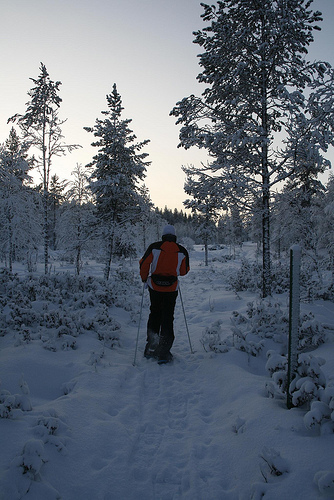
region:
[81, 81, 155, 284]
a snow covered tree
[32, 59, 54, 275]
a snow covered tree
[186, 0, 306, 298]
a snow covered tree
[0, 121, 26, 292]
a snow covered tree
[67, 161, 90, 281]
a snow covered tree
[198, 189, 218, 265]
a snow covered tree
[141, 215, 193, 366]
a long distance skier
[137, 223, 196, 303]
a skier with an orange jacket on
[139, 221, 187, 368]
a skier wearing black pants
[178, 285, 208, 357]
a long black ski pole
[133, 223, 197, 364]
person walking in snow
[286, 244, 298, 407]
post to the right of trail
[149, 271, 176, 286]
person wearing a black fanny pack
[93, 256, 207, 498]
path through the snow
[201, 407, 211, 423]
footprint in the snow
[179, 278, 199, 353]
person holding 2 trekking poles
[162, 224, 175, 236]
white knit hat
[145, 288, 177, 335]
black snow pants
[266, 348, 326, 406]
snow cover shrub next to post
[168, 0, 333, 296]
tall tree to the right of path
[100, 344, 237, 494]
tracks in the snow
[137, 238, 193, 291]
orange, white and black parka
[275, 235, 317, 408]
snow covered pole within brush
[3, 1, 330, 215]
grey sky with early morning light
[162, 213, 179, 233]
white knitted cap with black pom pom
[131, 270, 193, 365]
white snow hiking poles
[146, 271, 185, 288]
black fanny pack around hiker's waist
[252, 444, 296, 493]
grass poking up through snow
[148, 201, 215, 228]
pine trees in the distance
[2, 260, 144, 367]
low lying brush covered in snow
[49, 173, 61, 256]
a snow covered tree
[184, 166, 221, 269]
a snow covered tree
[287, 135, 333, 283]
a snow covered tree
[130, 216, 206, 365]
a skier going uphill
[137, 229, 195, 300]
a skier with an orange and black jacket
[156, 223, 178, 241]
a white cap on a skier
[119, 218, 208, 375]
Skiing in the snow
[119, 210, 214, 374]
Cross-country skiing in the snow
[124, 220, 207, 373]
Cross-country skiing outside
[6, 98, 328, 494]
Skiing on a trail in the snow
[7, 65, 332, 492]
Cross-country skiing in the forest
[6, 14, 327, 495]
Cross-country skiing among the trees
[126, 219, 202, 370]
Skiier in orange jacket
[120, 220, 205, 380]
Cross-country skier in a white hat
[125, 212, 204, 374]
Skier with poles